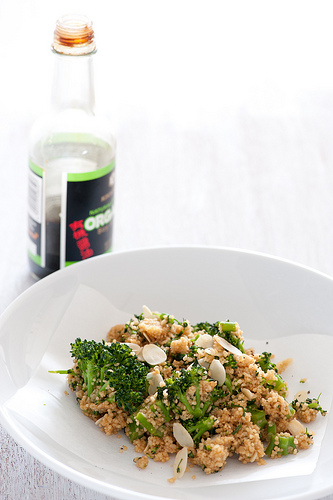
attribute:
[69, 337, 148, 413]
broccoli — biggest chunk, green, gob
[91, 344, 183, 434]
broccoli — green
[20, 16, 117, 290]
bottle — sauce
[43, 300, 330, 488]
food — brown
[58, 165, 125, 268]
label — black, green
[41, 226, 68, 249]
condiment — liquid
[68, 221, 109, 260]
symbols — red, asian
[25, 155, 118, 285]
label — black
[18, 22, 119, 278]
bottle — open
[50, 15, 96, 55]
top — open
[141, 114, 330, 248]
top — grey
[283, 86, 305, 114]
ground — green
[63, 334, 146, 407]
broccoli — green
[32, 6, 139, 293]
bottle — clear, glass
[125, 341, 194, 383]
almonds — slivered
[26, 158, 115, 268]
label — mostly black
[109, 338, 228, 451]
food — prepared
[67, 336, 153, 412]
broccoli — largest peice, green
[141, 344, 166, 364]
almonds — sliced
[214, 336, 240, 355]
almonds — sliced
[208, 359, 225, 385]
almonds — sliced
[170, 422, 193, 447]
almonds — sliced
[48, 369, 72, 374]
broccoli stem — green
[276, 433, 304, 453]
celery — peice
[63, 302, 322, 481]
meal — prepared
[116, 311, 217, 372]
almonds — three, sliced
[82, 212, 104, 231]
letters — white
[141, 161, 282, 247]
table — white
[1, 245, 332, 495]
bowl — white, small, porcelain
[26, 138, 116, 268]
label — black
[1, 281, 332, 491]
napkin — square